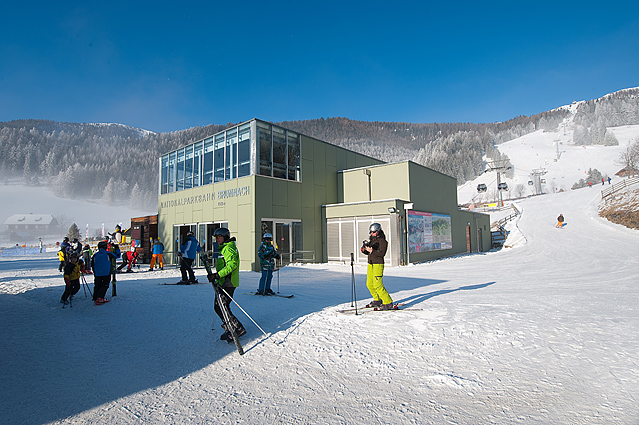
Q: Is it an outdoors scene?
A: Yes, it is outdoors.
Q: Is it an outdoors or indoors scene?
A: It is outdoors.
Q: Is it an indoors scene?
A: No, it is outdoors.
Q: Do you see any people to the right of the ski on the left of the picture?
A: Yes, there is a person to the right of the ski.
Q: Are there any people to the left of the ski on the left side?
A: No, the person is to the right of the ski.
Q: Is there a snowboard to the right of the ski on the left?
A: No, there is a person to the right of the ski.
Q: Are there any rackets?
A: No, there are no rackets.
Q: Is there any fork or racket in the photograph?
A: No, there are no rackets or forks.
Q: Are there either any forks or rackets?
A: No, there are no rackets or forks.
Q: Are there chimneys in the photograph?
A: No, there are no chimneys.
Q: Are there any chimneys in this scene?
A: No, there are no chimneys.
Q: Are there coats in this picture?
A: Yes, there is a coat.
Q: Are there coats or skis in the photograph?
A: Yes, there is a coat.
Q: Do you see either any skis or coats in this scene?
A: Yes, there is a coat.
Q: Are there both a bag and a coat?
A: No, there is a coat but no bags.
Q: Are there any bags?
A: No, there are no bags.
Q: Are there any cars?
A: No, there are no cars.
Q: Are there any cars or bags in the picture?
A: No, there are no cars or bags.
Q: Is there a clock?
A: No, there are no clocks.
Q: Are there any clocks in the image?
A: No, there are no clocks.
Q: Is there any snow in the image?
A: Yes, there is snow.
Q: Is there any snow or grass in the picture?
A: Yes, there is snow.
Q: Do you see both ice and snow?
A: No, there is snow but no ice.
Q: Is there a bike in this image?
A: No, there are no bikes.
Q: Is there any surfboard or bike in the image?
A: No, there are no bikes or surfboards.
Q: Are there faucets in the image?
A: No, there are no faucets.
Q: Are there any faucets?
A: No, there are no faucets.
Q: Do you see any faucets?
A: No, there are no faucets.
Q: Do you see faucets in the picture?
A: No, there are no faucets.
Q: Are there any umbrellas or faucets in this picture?
A: No, there are no faucets or umbrellas.